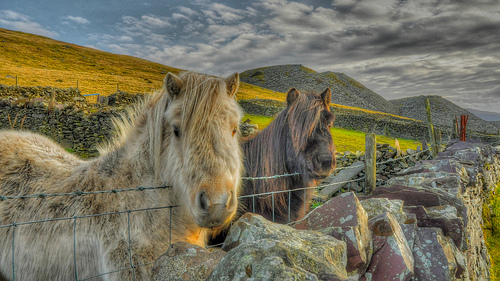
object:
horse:
[236, 84, 338, 217]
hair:
[243, 105, 312, 209]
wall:
[150, 137, 493, 279]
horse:
[1, 68, 245, 280]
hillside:
[1, 30, 499, 196]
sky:
[1, 1, 499, 124]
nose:
[312, 152, 334, 170]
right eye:
[171, 123, 182, 139]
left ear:
[318, 85, 334, 105]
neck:
[244, 112, 307, 215]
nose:
[197, 188, 234, 216]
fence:
[5, 111, 483, 280]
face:
[295, 101, 340, 176]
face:
[168, 94, 243, 227]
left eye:
[229, 125, 240, 139]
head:
[153, 68, 245, 223]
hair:
[178, 70, 221, 145]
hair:
[98, 92, 169, 156]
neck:
[92, 118, 185, 248]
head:
[284, 84, 339, 183]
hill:
[231, 63, 360, 113]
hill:
[384, 83, 496, 135]